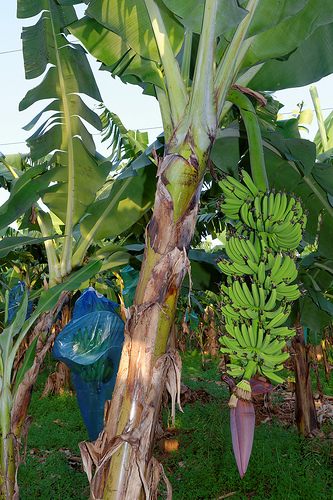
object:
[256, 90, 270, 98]
wall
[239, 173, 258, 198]
bananas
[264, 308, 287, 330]
bananas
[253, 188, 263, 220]
bananas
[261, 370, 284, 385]
bananas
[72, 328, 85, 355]
bananas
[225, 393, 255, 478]
tip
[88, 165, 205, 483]
trunk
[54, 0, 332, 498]
tree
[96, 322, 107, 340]
bananas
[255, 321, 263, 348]
banana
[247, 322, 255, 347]
banana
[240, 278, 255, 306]
banana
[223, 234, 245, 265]
banana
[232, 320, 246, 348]
banana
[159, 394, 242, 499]
bushing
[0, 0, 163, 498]
green shrubbery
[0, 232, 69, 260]
leaf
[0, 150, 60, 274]
leaf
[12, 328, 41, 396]
leaf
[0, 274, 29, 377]
leaf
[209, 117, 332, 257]
leaf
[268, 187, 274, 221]
bananas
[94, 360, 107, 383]
bananas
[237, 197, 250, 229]
bananas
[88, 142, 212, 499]
trunk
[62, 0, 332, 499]
banana tree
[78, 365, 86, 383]
bananas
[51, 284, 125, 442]
bag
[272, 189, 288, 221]
bananas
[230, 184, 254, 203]
banana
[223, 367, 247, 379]
bananas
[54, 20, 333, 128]
tops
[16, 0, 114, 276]
large leaves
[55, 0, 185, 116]
large leaves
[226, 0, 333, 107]
large leaves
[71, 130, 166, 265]
large leaves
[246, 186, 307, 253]
bunch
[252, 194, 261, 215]
banana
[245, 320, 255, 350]
banana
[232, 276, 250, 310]
banana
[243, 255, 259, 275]
banana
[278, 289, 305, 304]
banana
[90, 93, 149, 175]
leaf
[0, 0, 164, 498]
tree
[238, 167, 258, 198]
banana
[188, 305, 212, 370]
trees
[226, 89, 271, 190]
branch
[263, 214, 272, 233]
banana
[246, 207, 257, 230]
banana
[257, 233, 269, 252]
banana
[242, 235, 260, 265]
banana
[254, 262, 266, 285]
banana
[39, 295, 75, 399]
trees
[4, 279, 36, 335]
plastic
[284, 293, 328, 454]
trees